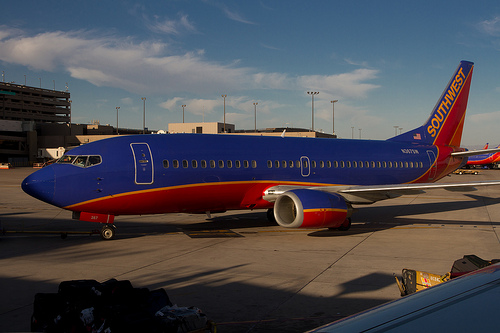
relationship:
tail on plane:
[432, 52, 478, 142] [17, 101, 486, 213]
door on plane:
[123, 138, 150, 189] [17, 101, 486, 213]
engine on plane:
[272, 177, 339, 237] [17, 101, 486, 213]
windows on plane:
[160, 155, 275, 174] [17, 101, 486, 213]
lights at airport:
[111, 86, 346, 112] [29, 61, 431, 154]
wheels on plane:
[92, 217, 130, 244] [17, 101, 486, 213]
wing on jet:
[310, 173, 499, 219] [17, 101, 486, 213]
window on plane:
[155, 147, 235, 167] [17, 101, 486, 213]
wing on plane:
[310, 173, 499, 219] [17, 101, 486, 213]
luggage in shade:
[49, 261, 199, 332] [68, 272, 303, 317]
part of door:
[136, 150, 152, 171] [123, 138, 150, 189]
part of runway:
[7, 171, 22, 181] [38, 226, 394, 330]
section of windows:
[268, 156, 297, 164] [160, 155, 275, 174]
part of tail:
[136, 150, 152, 171] [432, 52, 478, 142]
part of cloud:
[182, 59, 246, 87] [118, 35, 317, 71]